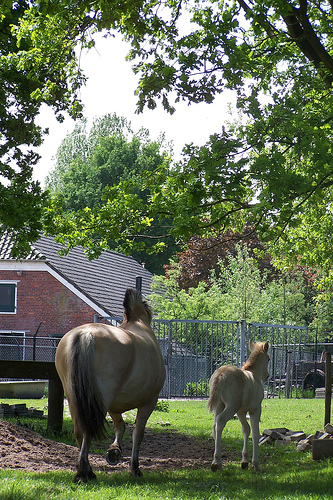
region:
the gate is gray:
[161, 307, 212, 403]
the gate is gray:
[165, 312, 212, 397]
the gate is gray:
[165, 314, 193, 401]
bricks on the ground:
[261, 411, 306, 465]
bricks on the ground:
[260, 404, 312, 466]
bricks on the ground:
[249, 413, 315, 454]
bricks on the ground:
[255, 415, 309, 451]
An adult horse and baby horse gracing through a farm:
[39, 277, 273, 490]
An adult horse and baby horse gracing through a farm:
[37, 275, 277, 486]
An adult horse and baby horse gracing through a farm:
[35, 282, 274, 487]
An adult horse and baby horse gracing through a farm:
[39, 281, 271, 486]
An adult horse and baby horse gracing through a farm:
[48, 283, 273, 485]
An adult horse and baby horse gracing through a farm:
[47, 282, 281, 487]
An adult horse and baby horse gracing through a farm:
[48, 282, 277, 491]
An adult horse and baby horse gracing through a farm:
[46, 282, 275, 481]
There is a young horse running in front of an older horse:
[34, 266, 286, 481]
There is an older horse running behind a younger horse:
[42, 271, 293, 488]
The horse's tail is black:
[58, 327, 134, 463]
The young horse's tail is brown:
[204, 367, 229, 413]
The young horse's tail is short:
[202, 363, 233, 419]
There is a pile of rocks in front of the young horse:
[254, 415, 316, 463]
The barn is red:
[1, 232, 142, 394]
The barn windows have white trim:
[0, 267, 25, 327]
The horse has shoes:
[102, 442, 127, 473]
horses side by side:
[32, 270, 293, 492]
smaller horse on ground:
[198, 334, 278, 473]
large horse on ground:
[47, 282, 156, 492]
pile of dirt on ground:
[0, 419, 215, 478]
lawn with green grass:
[161, 408, 327, 490]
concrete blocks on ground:
[257, 420, 329, 455]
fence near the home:
[1, 325, 83, 383]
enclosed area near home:
[99, 307, 315, 397]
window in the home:
[4, 278, 28, 319]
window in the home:
[1, 324, 35, 357]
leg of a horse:
[77, 407, 106, 469]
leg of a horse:
[98, 408, 130, 466]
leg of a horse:
[125, 419, 157, 474]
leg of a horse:
[207, 427, 237, 474]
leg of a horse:
[236, 423, 257, 478]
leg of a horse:
[248, 421, 273, 465]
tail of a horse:
[49, 342, 116, 436]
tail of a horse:
[196, 362, 237, 411]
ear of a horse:
[262, 331, 271, 353]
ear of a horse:
[248, 333, 257, 358]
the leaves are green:
[17, 10, 79, 99]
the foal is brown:
[212, 332, 272, 467]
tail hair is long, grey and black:
[67, 333, 108, 442]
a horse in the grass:
[202, 339, 279, 478]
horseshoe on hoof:
[106, 449, 121, 466]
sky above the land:
[84, 58, 142, 112]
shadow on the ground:
[152, 457, 208, 493]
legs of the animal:
[200, 426, 280, 460]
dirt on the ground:
[1, 427, 60, 473]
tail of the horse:
[34, 315, 131, 452]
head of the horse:
[225, 336, 290, 384]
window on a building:
[0, 270, 36, 326]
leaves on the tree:
[92, 171, 296, 250]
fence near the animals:
[161, 303, 251, 358]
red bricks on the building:
[24, 284, 66, 319]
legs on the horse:
[194, 409, 280, 466]